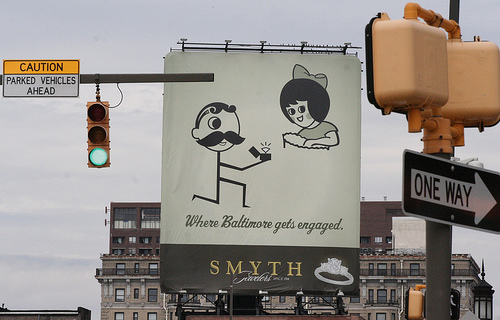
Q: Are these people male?
A: No, they are both male and female.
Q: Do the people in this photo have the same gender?
A: No, they are both male and female.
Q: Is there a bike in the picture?
A: No, there are no bikes.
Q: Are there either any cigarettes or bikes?
A: No, there are no bikes or cigarettes.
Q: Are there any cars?
A: No, there are no cars.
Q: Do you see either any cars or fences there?
A: No, there are no cars or fences.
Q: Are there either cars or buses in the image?
A: No, there are no cars or buses.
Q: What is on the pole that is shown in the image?
A: The sign is on the pole.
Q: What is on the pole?
A: The sign is on the pole.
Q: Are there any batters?
A: No, there are no batters.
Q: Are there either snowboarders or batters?
A: No, there are no batters or snowboarders.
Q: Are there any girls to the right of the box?
A: Yes, there is a girl to the right of the box.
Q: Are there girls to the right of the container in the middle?
A: Yes, there is a girl to the right of the box.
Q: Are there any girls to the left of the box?
A: No, the girl is to the right of the box.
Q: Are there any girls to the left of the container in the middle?
A: No, the girl is to the right of the box.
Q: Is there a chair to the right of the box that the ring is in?
A: No, there is a girl to the right of the box.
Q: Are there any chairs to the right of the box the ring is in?
A: No, there is a girl to the right of the box.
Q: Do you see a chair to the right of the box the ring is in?
A: No, there is a girl to the right of the box.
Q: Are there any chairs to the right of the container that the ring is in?
A: No, there is a girl to the right of the box.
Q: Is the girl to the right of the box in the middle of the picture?
A: Yes, the girl is to the right of the box.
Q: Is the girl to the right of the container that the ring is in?
A: Yes, the girl is to the right of the box.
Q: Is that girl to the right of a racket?
A: No, the girl is to the right of the box.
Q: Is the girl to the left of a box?
A: No, the girl is to the right of a box.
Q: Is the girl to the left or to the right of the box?
A: The girl is to the right of the box.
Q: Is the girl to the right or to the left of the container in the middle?
A: The girl is to the right of the box.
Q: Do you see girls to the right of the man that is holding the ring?
A: Yes, there is a girl to the right of the man.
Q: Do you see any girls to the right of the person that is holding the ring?
A: Yes, there is a girl to the right of the man.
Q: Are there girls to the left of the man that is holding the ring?
A: No, the girl is to the right of the man.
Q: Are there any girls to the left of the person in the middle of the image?
A: No, the girl is to the right of the man.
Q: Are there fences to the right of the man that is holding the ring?
A: No, there is a girl to the right of the man.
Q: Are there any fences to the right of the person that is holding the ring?
A: No, there is a girl to the right of the man.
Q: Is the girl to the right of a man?
A: Yes, the girl is to the right of a man.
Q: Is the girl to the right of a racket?
A: No, the girl is to the right of a man.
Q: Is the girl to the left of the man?
A: No, the girl is to the right of the man.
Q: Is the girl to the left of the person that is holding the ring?
A: No, the girl is to the right of the man.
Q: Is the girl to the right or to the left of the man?
A: The girl is to the right of the man.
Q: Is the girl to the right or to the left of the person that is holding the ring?
A: The girl is to the right of the man.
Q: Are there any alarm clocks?
A: No, there are no alarm clocks.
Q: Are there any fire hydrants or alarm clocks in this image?
A: No, there are no alarm clocks or fire hydrants.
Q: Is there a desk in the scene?
A: No, there are no desks.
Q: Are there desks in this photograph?
A: No, there are no desks.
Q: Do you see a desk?
A: No, there are no desks.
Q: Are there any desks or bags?
A: No, there are no desks or bags.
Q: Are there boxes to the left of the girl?
A: Yes, there is a box to the left of the girl.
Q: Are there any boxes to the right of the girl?
A: No, the box is to the left of the girl.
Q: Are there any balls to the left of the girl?
A: No, there is a box to the left of the girl.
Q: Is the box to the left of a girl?
A: Yes, the box is to the left of a girl.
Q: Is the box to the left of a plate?
A: No, the box is to the left of a girl.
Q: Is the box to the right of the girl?
A: No, the box is to the left of the girl.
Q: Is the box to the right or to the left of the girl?
A: The box is to the left of the girl.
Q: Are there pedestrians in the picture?
A: No, there are no pedestrians.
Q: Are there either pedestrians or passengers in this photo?
A: No, there are no pedestrians or passengers.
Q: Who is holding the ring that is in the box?
A: The man is holding the ring.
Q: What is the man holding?
A: The man is holding the ring.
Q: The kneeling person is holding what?
A: The man is holding the ring.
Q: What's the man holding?
A: The man is holding the ring.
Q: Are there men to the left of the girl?
A: Yes, there is a man to the left of the girl.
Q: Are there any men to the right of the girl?
A: No, the man is to the left of the girl.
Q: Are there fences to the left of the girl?
A: No, there is a man to the left of the girl.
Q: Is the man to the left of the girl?
A: Yes, the man is to the left of the girl.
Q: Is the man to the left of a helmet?
A: No, the man is to the left of the girl.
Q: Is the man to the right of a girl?
A: No, the man is to the left of a girl.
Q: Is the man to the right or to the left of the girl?
A: The man is to the left of the girl.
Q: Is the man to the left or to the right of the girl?
A: The man is to the left of the girl.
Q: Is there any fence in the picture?
A: No, there are no fences.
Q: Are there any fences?
A: No, there are no fences.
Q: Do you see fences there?
A: No, there are no fences.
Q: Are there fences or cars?
A: No, there are no fences or cars.